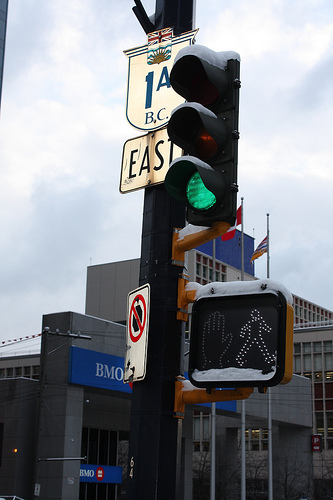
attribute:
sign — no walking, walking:
[181, 277, 293, 391]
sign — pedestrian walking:
[184, 279, 291, 404]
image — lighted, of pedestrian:
[232, 305, 275, 369]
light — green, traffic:
[178, 168, 221, 213]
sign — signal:
[164, 43, 243, 257]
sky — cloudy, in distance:
[11, 4, 118, 252]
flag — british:
[144, 28, 171, 46]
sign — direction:
[118, 127, 176, 189]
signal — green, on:
[180, 169, 221, 220]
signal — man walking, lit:
[232, 305, 283, 369]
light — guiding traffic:
[186, 286, 295, 382]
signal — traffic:
[164, 44, 240, 262]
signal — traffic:
[177, 279, 299, 403]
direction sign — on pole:
[118, 128, 182, 190]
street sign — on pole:
[119, 29, 199, 134]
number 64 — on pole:
[126, 454, 135, 480]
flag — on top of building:
[249, 209, 277, 281]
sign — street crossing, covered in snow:
[188, 289, 292, 388]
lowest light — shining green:
[165, 153, 227, 217]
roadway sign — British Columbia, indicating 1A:
[121, 27, 205, 132]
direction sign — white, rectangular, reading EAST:
[120, 131, 178, 192]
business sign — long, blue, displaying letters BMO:
[70, 345, 237, 414]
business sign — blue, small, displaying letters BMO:
[79, 463, 122, 482]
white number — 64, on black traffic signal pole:
[127, 454, 137, 481]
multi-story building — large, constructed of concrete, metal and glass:
[1, 211, 307, 494]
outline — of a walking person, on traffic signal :
[233, 302, 273, 369]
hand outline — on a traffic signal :
[198, 308, 234, 370]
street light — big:
[162, 41, 242, 240]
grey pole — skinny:
[206, 405, 217, 496]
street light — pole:
[172, 375, 191, 417]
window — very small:
[312, 370, 319, 379]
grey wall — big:
[37, 359, 61, 487]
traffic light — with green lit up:
[167, 44, 237, 231]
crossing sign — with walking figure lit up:
[188, 280, 293, 390]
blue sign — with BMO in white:
[79, 466, 121, 484]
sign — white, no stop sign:
[121, 282, 151, 381]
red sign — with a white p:
[311, 432, 321, 452]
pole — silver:
[236, 200, 250, 275]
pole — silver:
[261, 211, 274, 276]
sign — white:
[111, 131, 200, 208]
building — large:
[78, 184, 328, 426]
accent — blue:
[200, 225, 253, 264]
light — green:
[164, 155, 224, 227]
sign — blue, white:
[64, 346, 243, 413]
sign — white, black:
[118, 286, 160, 385]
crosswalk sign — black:
[176, 279, 298, 403]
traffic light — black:
[158, 43, 247, 231]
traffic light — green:
[173, 164, 222, 212]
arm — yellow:
[166, 224, 226, 271]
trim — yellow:
[171, 281, 292, 409]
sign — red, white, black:
[119, 279, 154, 384]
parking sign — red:
[309, 432, 325, 455]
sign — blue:
[79, 467, 125, 482]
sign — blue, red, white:
[74, 461, 128, 482]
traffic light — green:
[166, 49, 247, 227]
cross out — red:
[127, 290, 148, 339]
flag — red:
[217, 206, 241, 244]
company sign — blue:
[67, 344, 243, 422]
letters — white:
[93, 359, 129, 384]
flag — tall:
[221, 202, 240, 240]